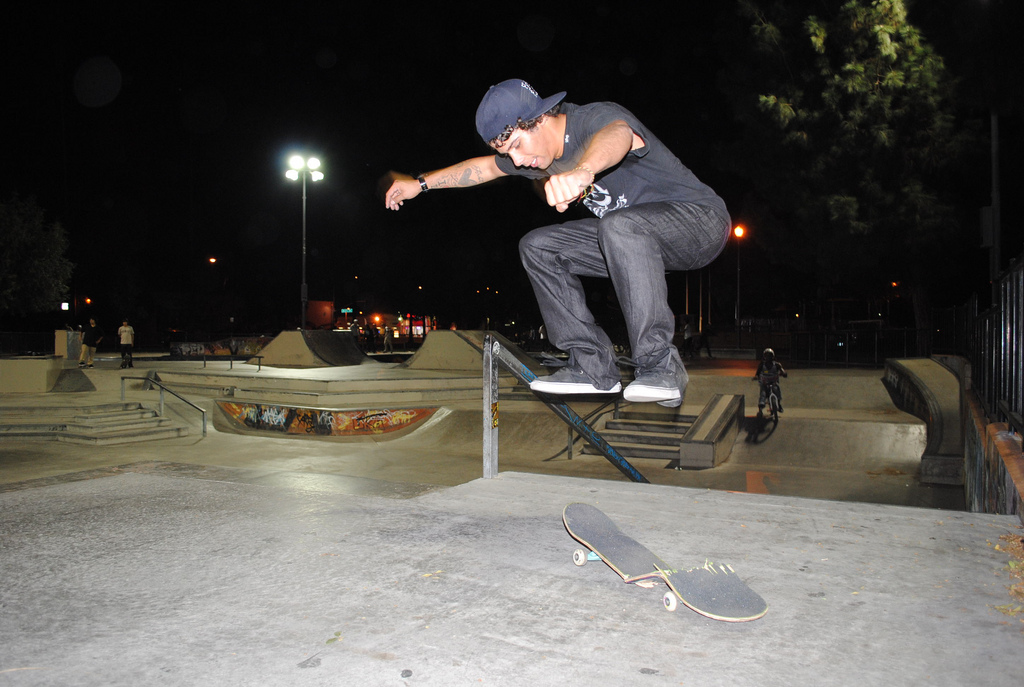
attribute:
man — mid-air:
[380, 72, 735, 412]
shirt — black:
[491, 96, 720, 222]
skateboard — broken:
[557, 495, 771, 627]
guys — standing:
[30, 292, 175, 413]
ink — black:
[414, 147, 494, 206]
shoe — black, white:
[526, 348, 626, 409]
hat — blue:
[460, 89, 610, 150]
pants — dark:
[498, 190, 816, 396]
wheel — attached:
[516, 526, 614, 565]